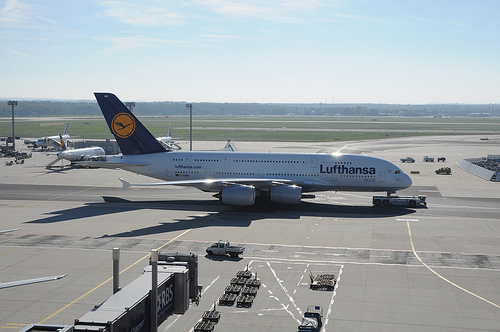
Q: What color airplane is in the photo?
A: White.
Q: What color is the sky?
A: Blue.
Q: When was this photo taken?
A: Daytime.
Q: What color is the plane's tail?
A: Blue.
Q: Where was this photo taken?
A: Airport.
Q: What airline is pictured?
A: Lufthansa.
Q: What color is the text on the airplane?
A: Blue.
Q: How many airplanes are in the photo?
A: One.